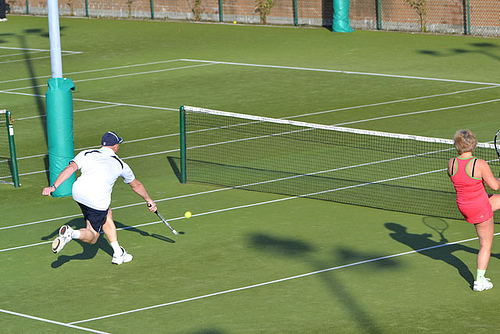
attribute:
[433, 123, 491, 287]
woman — playing, player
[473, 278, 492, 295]
shoes — white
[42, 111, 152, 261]
man — player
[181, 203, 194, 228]
ball — ellow, flight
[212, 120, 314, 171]
net — white, part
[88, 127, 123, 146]
hat — blue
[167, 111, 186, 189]
pole — gree, padded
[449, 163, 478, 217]
outfit — pik